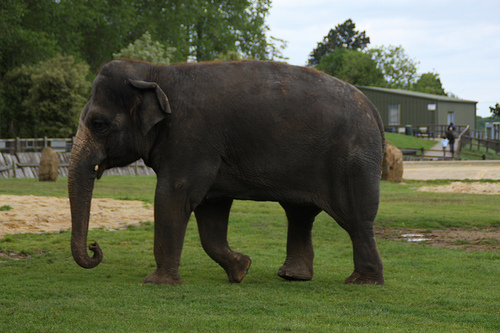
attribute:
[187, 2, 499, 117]
sky — blue, clear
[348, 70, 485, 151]
building — green